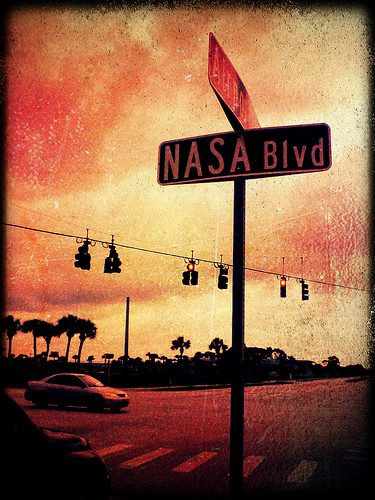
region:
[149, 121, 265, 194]
capital letters on the sign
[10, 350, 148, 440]
car on the street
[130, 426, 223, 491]
lines on the ground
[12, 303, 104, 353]
trees next to the road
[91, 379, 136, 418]
front of the car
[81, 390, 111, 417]
tire on the car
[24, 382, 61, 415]
back tire of the car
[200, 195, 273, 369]
pole under the sign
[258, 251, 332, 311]
lights above the ground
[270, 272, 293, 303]
light on the rope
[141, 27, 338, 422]
two city street signs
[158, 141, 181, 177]
the letter N of a sign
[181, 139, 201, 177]
the letter A of a sign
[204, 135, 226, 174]
the letter S of a sign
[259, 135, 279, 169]
the letter B of a sign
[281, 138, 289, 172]
the letter L of a sign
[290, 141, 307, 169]
the letter V of a sign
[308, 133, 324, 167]
the letter D of a sign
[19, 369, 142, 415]
a car driving down the street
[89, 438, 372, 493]
the crosswalk on a city street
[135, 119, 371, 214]
nasa blvd street sign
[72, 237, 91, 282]
traffic signal hanging on line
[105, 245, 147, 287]
traffic signal hanging on line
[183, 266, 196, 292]
traffic signal hanging on line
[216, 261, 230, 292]
traffic signal hanging on line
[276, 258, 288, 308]
traffic signal hanging on line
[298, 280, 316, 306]
traffic signal hanging on line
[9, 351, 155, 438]
car crossing intersection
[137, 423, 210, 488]
white lines painted on street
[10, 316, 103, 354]
palm trees on left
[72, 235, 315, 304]
The street lights are hanging.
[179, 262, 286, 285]
The lights are on.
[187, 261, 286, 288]
The lights are red.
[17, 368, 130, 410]
The car is driving.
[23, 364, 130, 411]
The car is in the intersection.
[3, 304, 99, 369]
The trees are tall.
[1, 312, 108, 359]
The trees are leafy.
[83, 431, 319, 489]
The paint is white.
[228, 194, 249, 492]
The pole is silver.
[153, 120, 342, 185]
The street sign is on the pole.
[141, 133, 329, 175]
NASA Blvd on the sign.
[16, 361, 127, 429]
Car crossing the road.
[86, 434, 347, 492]
Lines on the road.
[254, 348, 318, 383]
Buildings next to the road.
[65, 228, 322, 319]
Stoplights above the road.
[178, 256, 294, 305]
The red lights are shining.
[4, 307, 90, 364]
The trees are tall.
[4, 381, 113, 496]
Car next to the camera.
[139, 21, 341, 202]
Two street signs on the pole.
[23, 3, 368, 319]
The sky is yellow and orange.